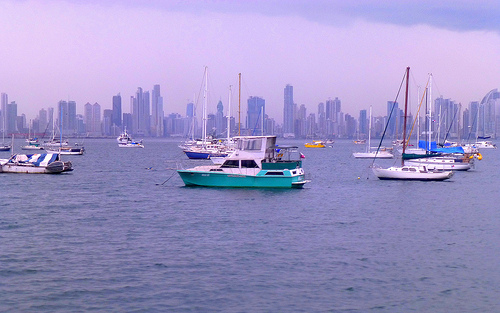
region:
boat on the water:
[166, 150, 310, 192]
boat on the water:
[371, 158, 452, 184]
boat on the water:
[407, 155, 472, 171]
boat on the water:
[3, 150, 70, 176]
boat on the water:
[42, 143, 85, 153]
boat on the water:
[116, 136, 146, 150]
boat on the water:
[1, 137, 15, 153]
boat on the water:
[351, 135, 366, 148]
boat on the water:
[115, 123, 135, 143]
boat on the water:
[474, 139, 495, 151]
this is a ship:
[173, 127, 301, 204]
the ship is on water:
[179, 135, 314, 197]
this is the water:
[257, 212, 384, 310]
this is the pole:
[384, 70, 420, 146]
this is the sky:
[307, 5, 387, 60]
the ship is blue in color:
[222, 172, 244, 187]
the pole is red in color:
[396, 62, 415, 129]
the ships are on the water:
[157, 84, 302, 194]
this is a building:
[277, 85, 299, 122]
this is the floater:
[46, 160, 71, 173]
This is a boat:
[188, 152, 313, 207]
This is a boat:
[0, 145, 78, 198]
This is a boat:
[53, 144, 119, 167]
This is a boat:
[114, 118, 147, 155]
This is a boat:
[168, 125, 239, 176]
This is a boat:
[368, 140, 459, 204]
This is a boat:
[410, 155, 491, 176]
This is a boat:
[351, 139, 391, 164]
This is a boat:
[294, 130, 339, 162]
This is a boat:
[423, 134, 493, 167]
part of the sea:
[401, 197, 411, 212]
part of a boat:
[258, 183, 272, 199]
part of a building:
[307, 137, 318, 158]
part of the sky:
[354, 262, 367, 280]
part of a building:
[126, 105, 140, 140]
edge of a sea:
[267, 244, 281, 275]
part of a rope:
[133, 179, 176, 189]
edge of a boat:
[309, 135, 346, 160]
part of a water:
[235, 236, 279, 293]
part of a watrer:
[286, 200, 326, 242]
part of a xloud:
[328, 10, 380, 78]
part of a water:
[322, 214, 347, 245]